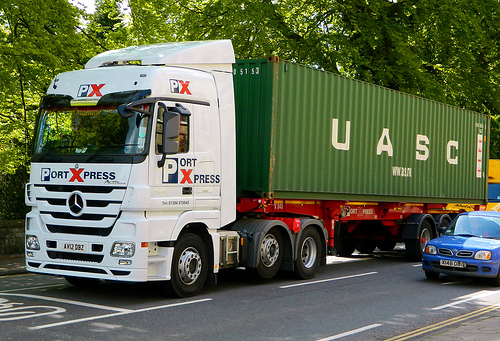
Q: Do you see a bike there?
A: No, there are no bikes.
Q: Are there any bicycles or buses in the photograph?
A: No, there are no bicycles or buses.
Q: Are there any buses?
A: No, there are no buses.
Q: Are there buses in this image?
A: No, there are no buses.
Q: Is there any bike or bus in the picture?
A: No, there are no buses or bikes.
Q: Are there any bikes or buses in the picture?
A: No, there are no buses or bikes.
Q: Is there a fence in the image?
A: No, there are no fences.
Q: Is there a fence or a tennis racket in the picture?
A: No, there are no fences or rackets.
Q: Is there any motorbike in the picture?
A: No, there are no motorcycles.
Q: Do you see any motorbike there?
A: No, there are no motorcycles.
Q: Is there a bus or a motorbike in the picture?
A: No, there are no motorcycles or buses.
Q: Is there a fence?
A: No, there are no fences.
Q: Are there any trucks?
A: Yes, there is a truck.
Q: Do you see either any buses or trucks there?
A: Yes, there is a truck.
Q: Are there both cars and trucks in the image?
A: Yes, there are both a truck and cars.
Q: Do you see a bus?
A: No, there are no buses.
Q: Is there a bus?
A: No, there are no buses.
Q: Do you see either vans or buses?
A: No, there are no buses or vans.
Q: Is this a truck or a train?
A: This is a truck.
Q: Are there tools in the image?
A: No, there are no tools.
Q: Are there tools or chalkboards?
A: No, there are no tools or chalkboards.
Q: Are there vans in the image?
A: No, there are no vans.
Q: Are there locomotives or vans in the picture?
A: No, there are no vans or locomotives.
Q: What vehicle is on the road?
A: The vehicle is a car.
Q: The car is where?
A: The car is on the road.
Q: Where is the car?
A: The car is on the road.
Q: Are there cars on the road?
A: Yes, there is a car on the road.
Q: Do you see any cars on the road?
A: Yes, there is a car on the road.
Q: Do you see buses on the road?
A: No, there is a car on the road.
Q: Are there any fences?
A: No, there are no fences.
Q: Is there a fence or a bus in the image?
A: No, there are no fences or buses.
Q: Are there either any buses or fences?
A: No, there are no fences or buses.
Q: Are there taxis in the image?
A: Yes, there is a taxi.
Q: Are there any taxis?
A: Yes, there is a taxi.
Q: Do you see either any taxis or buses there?
A: Yes, there is a taxi.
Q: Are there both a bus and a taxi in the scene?
A: No, there is a taxi but no buses.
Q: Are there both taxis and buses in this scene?
A: No, there is a taxi but no buses.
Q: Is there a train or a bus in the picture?
A: No, there are no buses or trains.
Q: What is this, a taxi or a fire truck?
A: This is a taxi.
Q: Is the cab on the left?
A: Yes, the cab is on the left of the image.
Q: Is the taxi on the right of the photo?
A: No, the taxi is on the left of the image.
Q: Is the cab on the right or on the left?
A: The cab is on the left of the image.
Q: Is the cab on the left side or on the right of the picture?
A: The cab is on the left of the image.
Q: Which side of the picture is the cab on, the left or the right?
A: The cab is on the left of the image.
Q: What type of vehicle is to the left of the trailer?
A: The vehicle is a taxi.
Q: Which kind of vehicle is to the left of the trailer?
A: The vehicle is a taxi.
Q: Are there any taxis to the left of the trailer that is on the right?
A: Yes, there is a taxi to the left of the trailer.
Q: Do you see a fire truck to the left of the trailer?
A: No, there is a taxi to the left of the trailer.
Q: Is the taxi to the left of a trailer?
A: Yes, the taxi is to the left of a trailer.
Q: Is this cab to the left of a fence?
A: No, the cab is to the left of a trailer.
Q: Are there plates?
A: Yes, there is a plate.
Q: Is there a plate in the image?
A: Yes, there is a plate.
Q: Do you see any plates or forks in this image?
A: Yes, there is a plate.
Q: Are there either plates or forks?
A: Yes, there is a plate.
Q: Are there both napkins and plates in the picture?
A: No, there is a plate but no napkins.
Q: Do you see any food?
A: No, there is no food.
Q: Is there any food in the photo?
A: No, there is no food.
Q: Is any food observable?
A: No, there is no food.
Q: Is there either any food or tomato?
A: No, there are no food or tomatoes.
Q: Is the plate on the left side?
A: Yes, the plate is on the left of the image.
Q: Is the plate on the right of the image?
A: No, the plate is on the left of the image.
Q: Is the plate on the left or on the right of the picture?
A: The plate is on the left of the image.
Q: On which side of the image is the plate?
A: The plate is on the left of the image.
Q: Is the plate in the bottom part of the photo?
A: Yes, the plate is in the bottom of the image.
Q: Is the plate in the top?
A: No, the plate is in the bottom of the image.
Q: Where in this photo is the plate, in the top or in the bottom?
A: The plate is in the bottom of the image.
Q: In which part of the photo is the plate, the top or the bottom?
A: The plate is in the bottom of the image.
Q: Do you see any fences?
A: No, there are no fences.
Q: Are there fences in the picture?
A: No, there are no fences.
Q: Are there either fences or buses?
A: No, there are no fences or buses.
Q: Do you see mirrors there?
A: Yes, there is a mirror.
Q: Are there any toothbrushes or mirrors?
A: Yes, there is a mirror.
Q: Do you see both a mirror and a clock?
A: No, there is a mirror but no clocks.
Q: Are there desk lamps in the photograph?
A: No, there are no desk lamps.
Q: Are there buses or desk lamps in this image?
A: No, there are no desk lamps or buses.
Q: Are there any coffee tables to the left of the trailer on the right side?
A: No, there is a mirror to the left of the trailer.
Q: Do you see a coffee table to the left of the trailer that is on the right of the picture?
A: No, there is a mirror to the left of the trailer.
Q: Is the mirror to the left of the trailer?
A: Yes, the mirror is to the left of the trailer.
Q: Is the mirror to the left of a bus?
A: No, the mirror is to the left of the trailer.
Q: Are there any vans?
A: No, there are no vans.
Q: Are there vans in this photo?
A: No, there are no vans.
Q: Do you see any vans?
A: No, there are no vans.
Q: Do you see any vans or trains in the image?
A: No, there are no vans or trains.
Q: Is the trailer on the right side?
A: Yes, the trailer is on the right of the image.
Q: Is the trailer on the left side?
A: No, the trailer is on the right of the image.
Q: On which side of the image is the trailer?
A: The trailer is on the right of the image.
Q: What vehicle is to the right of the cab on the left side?
A: The vehicle is a trailer.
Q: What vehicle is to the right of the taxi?
A: The vehicle is a trailer.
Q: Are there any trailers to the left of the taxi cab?
A: No, the trailer is to the right of the taxi cab.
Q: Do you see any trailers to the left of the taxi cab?
A: No, the trailer is to the right of the taxi cab.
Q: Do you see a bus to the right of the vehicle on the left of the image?
A: No, there is a trailer to the right of the taxi cab.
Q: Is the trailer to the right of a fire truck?
A: No, the trailer is to the right of the taxi.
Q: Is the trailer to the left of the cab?
A: No, the trailer is to the right of the cab.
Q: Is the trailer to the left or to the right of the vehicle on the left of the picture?
A: The trailer is to the right of the taxi cab.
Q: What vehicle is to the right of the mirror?
A: The vehicle is a trailer.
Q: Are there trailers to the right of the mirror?
A: Yes, there is a trailer to the right of the mirror.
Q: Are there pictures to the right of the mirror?
A: No, there is a trailer to the right of the mirror.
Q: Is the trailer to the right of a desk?
A: No, the trailer is to the right of a mirror.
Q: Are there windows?
A: Yes, there is a window.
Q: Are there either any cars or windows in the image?
A: Yes, there is a window.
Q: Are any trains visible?
A: No, there are no trains.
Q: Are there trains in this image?
A: No, there are no trains.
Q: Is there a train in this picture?
A: No, there are no trains.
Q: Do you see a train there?
A: No, there are no trains.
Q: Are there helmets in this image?
A: No, there are no helmets.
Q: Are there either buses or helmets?
A: No, there are no helmets or buses.